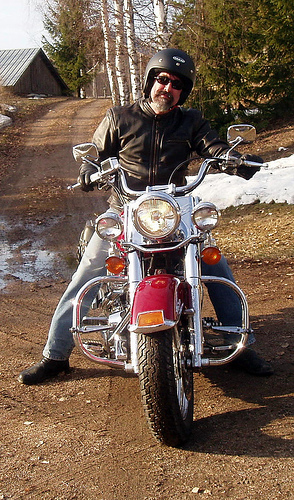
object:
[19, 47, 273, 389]
man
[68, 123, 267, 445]
motorcycle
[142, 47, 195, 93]
helmet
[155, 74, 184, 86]
sunglasses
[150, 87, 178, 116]
hair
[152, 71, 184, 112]
face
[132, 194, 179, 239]
headlight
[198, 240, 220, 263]
signal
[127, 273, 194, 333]
fender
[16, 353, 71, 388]
boot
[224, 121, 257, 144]
mirror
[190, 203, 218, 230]
headlights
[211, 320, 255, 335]
rest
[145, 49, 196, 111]
head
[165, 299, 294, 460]
shadow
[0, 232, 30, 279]
water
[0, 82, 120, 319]
road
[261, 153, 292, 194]
snow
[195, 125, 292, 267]
ground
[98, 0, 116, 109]
trunks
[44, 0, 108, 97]
trees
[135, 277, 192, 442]
wheel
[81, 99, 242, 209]
jacket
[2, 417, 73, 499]
dirt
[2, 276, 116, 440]
tracks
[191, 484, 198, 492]
stone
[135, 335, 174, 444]
grooves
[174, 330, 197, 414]
rims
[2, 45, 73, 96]
barn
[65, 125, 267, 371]
frame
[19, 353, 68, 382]
shoes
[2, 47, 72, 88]
roof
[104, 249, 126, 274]
lights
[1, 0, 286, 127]
background